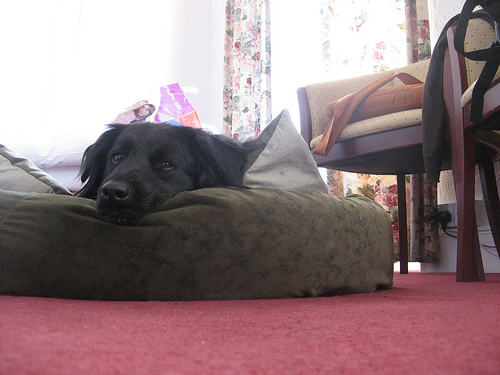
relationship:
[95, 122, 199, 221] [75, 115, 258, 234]
head of a dog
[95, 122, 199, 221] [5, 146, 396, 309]
head on a bed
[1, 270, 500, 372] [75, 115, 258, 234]
floor next to dog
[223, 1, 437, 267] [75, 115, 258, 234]
drapes are near dog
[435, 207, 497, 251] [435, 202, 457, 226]
power cord in an outlet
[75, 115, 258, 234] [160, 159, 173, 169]
dog has an eye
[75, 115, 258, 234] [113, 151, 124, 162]
dog has an eye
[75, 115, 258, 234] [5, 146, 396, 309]
dog on a bed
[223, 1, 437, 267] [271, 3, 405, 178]
drapes are covering window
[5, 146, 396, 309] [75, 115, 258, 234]
bed for dog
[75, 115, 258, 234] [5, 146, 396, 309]
dog on its bed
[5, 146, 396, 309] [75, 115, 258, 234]
bed has a dog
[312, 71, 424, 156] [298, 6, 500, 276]
bag on a chair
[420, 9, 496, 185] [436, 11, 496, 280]
jacket on a chair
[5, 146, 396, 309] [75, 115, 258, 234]
bed for a dog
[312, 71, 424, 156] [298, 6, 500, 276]
bag on chair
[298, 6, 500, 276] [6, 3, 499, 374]
chair in a room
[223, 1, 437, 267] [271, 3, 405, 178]
drapes are by a window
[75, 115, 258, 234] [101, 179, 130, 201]
dog has a nose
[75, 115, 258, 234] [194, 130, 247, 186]
dog has an ear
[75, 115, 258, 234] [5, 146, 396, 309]
dog resting on bed